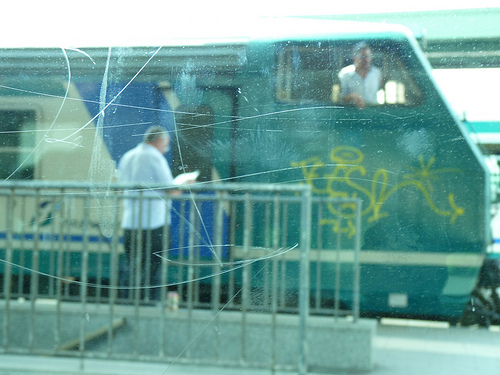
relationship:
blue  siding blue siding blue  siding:
[77, 79, 230, 257] [77, 78, 227, 258]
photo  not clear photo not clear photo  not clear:
[1, 2, 499, 373] [1, 2, 499, 373]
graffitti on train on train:
[282, 142, 461, 248] [0, 36, 489, 314]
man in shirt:
[120, 125, 187, 305] [112, 140, 177, 230]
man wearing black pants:
[120, 125, 187, 305] [124, 223, 165, 297]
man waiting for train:
[120, 125, 187, 305] [0, 36, 489, 314]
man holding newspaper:
[120, 125, 187, 305] [170, 169, 202, 192]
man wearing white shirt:
[120, 125, 187, 305] [340, 64, 379, 104]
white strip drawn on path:
[234, 242, 487, 268] [4, 294, 494, 370]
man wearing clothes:
[120, 125, 187, 305] [116, 145, 172, 297]